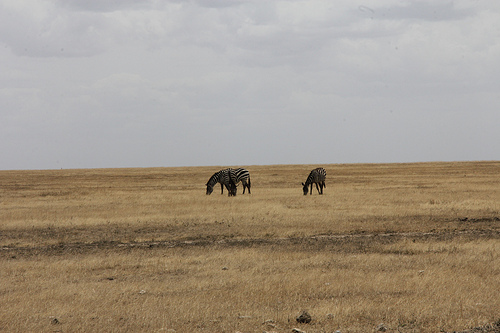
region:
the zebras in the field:
[189, 154, 336, 202]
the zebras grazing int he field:
[194, 154, 334, 203]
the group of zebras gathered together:
[197, 154, 332, 204]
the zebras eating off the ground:
[299, 178, 311, 197]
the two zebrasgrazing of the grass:
[200, 161, 260, 202]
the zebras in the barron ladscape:
[199, 159, 333, 204]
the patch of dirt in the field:
[4, 224, 197, 260]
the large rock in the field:
[290, 302, 317, 327]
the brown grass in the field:
[2, 252, 468, 331]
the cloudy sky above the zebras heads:
[0, 0, 497, 165]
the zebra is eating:
[196, 160, 265, 214]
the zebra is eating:
[284, 146, 344, 225]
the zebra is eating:
[285, 165, 367, 237]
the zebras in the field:
[167, 133, 387, 251]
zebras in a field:
[199, 158, 336, 199]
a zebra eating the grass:
[296, 160, 326, 197]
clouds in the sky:
[19, 31, 494, 153]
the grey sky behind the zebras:
[7, 36, 463, 138]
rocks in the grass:
[277, 298, 317, 330]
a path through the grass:
[25, 220, 494, 224]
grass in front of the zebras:
[21, 203, 496, 298]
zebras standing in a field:
[196, 148, 351, 215]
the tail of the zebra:
[321, 176, 328, 188]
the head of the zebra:
[203, 175, 215, 195]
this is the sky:
[163, 38, 445, 140]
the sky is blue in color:
[344, 66, 439, 123]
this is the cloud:
[164, 28, 229, 83]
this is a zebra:
[299, 162, 331, 195]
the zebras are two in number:
[193, 155, 341, 204]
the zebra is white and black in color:
[234, 166, 247, 183]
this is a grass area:
[337, 253, 446, 323]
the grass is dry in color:
[374, 255, 479, 303]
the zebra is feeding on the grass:
[296, 180, 313, 197]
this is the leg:
[219, 180, 223, 194]